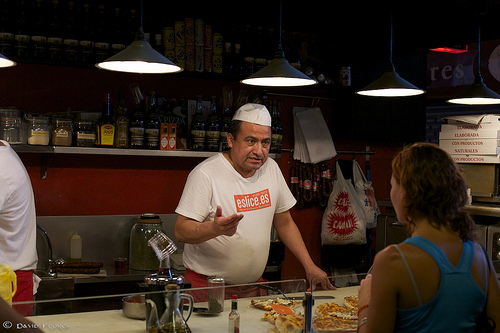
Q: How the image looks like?
A: Restaurant.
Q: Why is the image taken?
A: Remembrance.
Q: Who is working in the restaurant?
A: Cook.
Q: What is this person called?
A: Cook.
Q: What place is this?
A: Diner.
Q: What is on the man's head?
A: Hat.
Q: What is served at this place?
A: Fast food.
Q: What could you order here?
A: Hamburger.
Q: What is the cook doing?
A: Taking an order.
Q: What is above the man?
A: Lights.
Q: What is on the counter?
A: Pizza.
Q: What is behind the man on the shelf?
A: Spices.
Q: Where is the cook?
A: Behind the counter.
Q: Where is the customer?
A: Across from the cook.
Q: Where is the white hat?
A: On the cook's head.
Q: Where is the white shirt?
A: On the cook.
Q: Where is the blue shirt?
A: On the woman.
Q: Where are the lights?
A: Above the cook.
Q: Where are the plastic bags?
A: Behind the cook.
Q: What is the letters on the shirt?
A: Eslice.es.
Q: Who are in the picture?
A: Two men and a woman.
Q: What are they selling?
A: Pizzas.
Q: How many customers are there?
A: One.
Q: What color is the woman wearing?
A: Blue.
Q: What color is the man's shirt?
A: White.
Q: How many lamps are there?
A: Five.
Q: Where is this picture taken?
A: At the pizza shop.